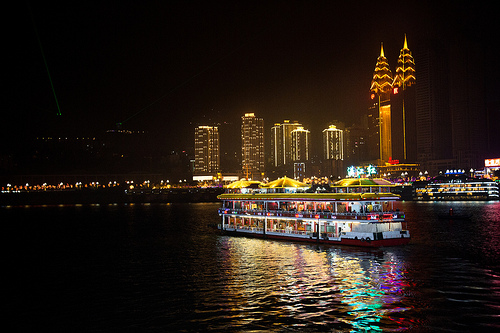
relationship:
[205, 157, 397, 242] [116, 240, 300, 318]
boat on water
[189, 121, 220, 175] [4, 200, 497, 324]
lit building across bay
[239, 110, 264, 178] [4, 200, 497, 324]
lit building across bay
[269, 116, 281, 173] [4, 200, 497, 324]
lit building across bay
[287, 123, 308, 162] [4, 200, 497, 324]
lit building across bay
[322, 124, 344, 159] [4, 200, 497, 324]
lit building across bay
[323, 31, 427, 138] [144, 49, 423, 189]
skyscraper near buildings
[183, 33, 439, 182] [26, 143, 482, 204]
buildings in background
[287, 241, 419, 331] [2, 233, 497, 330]
lights on water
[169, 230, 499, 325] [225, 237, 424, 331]
ripples in waves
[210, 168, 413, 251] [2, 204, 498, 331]
boat on water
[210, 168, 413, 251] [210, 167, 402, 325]
boat with lights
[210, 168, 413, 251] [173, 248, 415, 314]
boat on water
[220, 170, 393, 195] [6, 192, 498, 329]
lights reflecting off water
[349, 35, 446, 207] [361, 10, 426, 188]
building surrounded by light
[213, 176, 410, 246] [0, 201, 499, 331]
boat floating down river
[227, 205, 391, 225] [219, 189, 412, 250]
passengers on boat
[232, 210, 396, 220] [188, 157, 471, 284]
lights on boat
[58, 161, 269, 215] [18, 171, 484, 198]
lights in distance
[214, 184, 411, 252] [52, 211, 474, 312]
boat in ocean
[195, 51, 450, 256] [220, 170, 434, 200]
boat in front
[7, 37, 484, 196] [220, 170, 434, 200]
city has front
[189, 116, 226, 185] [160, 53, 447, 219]
building in city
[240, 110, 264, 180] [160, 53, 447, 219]
building in city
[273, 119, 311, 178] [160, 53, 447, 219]
building in city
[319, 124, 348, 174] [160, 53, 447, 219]
building in city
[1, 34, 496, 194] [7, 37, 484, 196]
lights in city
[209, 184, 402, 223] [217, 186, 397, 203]
boat has roof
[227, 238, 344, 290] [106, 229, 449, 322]
reflection on water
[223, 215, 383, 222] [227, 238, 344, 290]
light has reflection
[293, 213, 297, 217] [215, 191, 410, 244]
light on ship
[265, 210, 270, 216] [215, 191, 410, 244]
light on ship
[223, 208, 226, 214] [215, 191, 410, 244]
light on ship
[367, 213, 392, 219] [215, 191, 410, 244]
light on ship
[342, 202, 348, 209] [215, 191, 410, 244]
light on ship